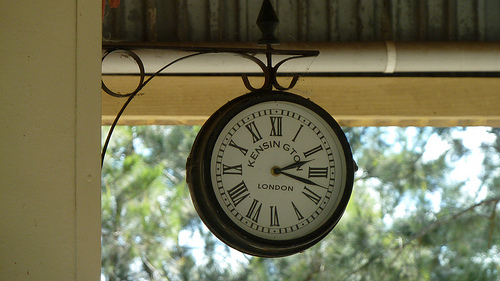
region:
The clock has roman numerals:
[172, 81, 371, 257]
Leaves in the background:
[369, 136, 471, 194]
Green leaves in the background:
[369, 135, 472, 196]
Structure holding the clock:
[108, 26, 331, 122]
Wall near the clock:
[6, 6, 224, 271]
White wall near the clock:
[11, 6, 225, 273]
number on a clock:
[292, 119, 312, 149]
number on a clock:
[292, 140, 329, 157]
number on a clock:
[305, 158, 338, 184]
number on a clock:
[290, 180, 336, 210]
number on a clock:
[281, 193, 308, 223]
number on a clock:
[263, 190, 284, 230]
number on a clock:
[242, 195, 267, 230]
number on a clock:
[225, 171, 246, 206]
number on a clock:
[217, 138, 254, 153]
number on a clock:
[266, 112, 283, 145]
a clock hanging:
[178, 82, 361, 262]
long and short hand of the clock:
[268, 155, 333, 195]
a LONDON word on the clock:
[254, 178, 296, 195]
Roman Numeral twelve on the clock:
[266, 112, 288, 141]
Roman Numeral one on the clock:
[289, 120, 307, 145]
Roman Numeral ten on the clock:
[225, 135, 252, 158]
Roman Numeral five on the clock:
[285, 195, 307, 224]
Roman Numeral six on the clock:
[266, 200, 283, 230]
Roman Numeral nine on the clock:
[217, 157, 247, 179]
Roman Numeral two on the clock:
[298, 140, 328, 161]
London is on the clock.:
[256, 182, 296, 197]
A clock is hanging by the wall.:
[184, 89, 359, 259]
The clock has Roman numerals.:
[183, 94, 360, 259]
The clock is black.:
[183, 87, 358, 264]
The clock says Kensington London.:
[245, 137, 305, 196]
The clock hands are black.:
[268, 159, 326, 190]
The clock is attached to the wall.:
[97, 34, 364, 258]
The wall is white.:
[2, 2, 109, 279]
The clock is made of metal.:
[102, 38, 361, 258]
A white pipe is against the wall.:
[104, 39, 499, 76]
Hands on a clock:
[259, 144, 326, 204]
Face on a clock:
[183, 80, 355, 269]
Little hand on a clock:
[269, 153, 320, 176]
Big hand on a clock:
[270, 165, 329, 190]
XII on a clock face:
[264, 107, 289, 140]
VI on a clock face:
[266, 199, 283, 229]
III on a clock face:
[305, 165, 331, 184]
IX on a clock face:
[216, 161, 251, 178]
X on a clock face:
[223, 135, 255, 153]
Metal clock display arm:
[80, 36, 319, 175]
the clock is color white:
[174, 84, 368, 265]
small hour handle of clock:
[268, 154, 317, 172]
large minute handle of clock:
[287, 169, 330, 194]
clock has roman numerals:
[202, 96, 354, 245]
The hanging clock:
[176, 82, 376, 247]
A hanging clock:
[184, 87, 374, 261]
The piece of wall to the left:
[3, 5, 121, 265]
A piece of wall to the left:
[2, 5, 122, 275]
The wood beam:
[94, 67, 498, 122]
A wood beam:
[98, 62, 493, 134]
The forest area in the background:
[96, 119, 491, 279]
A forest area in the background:
[86, 114, 497, 277]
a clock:
[200, 83, 365, 260]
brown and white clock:
[189, 82, 359, 267]